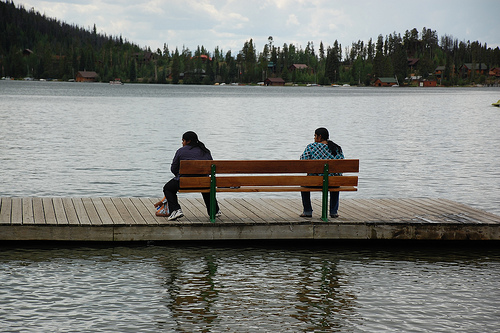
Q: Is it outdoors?
A: Yes, it is outdoors.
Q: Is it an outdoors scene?
A: Yes, it is outdoors.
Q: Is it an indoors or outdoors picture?
A: It is outdoors.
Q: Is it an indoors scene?
A: No, it is outdoors.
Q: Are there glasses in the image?
A: No, there are no glasses.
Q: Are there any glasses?
A: No, there are no glasses.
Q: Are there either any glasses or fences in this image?
A: No, there are no glasses or fences.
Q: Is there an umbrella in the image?
A: No, there are no umbrellas.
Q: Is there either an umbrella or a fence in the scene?
A: No, there are no umbrellas or fences.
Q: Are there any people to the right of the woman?
A: Yes, there are people to the right of the woman.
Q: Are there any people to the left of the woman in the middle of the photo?
A: No, the people are to the right of the woman.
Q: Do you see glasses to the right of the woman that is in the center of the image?
A: No, there are people to the right of the woman.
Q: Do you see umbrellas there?
A: No, there are no umbrellas.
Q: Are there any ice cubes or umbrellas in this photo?
A: No, there are no umbrellas or ice cubes.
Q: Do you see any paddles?
A: No, there are no paddles.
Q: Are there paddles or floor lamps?
A: No, there are no paddles or floor lamps.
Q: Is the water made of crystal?
A: Yes, the water is made of crystal.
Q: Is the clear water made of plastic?
A: No, the water is made of crystal.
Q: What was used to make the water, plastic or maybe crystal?
A: The water is made of crystal.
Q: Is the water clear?
A: Yes, the water is clear.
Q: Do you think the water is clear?
A: Yes, the water is clear.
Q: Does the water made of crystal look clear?
A: Yes, the water is clear.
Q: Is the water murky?
A: No, the water is clear.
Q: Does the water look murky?
A: No, the water is clear.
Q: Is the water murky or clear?
A: The water is clear.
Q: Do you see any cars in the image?
A: No, there are no cars.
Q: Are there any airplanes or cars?
A: No, there are no cars or airplanes.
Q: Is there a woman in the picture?
A: Yes, there is a woman.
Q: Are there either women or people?
A: Yes, there is a woman.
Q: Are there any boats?
A: No, there are no boats.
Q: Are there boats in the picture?
A: No, there are no boats.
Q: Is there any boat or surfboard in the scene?
A: No, there are no boats or surfboards.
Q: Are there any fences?
A: No, there are no fences.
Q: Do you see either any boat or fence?
A: No, there are no fences or boats.